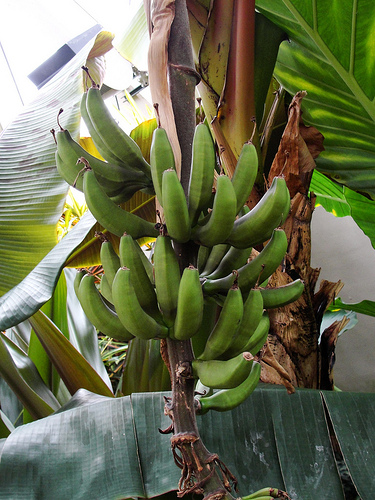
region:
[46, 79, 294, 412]
A large group of small green bananas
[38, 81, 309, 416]
Unripe green bananas growing on the tree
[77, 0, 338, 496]
A banana tree with many unripe bananas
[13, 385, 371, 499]
A large green banana leaf behind the banana tree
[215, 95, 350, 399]
A large brown banana tree trunk behind the bananas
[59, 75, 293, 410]
The green bananas all face upwards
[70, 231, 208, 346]
The bundle of green bananas is curving upwards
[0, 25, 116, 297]
A large yellow green banana leaf in the background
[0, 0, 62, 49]
The sun is shining too brightly to see the sky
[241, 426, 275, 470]
Small white splotches on the banana leaf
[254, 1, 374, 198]
large green leaf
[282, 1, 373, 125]
spine of a green leaf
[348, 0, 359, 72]
vein growing out from spine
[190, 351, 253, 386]
green banana attached to a brown stem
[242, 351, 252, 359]
brown nub on the end of a banana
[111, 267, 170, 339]
banana growing on a banana plant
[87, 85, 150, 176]
banana next to a banana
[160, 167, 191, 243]
banana under a banana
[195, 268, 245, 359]
banana to the right of a banana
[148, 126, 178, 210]
banana to the left of a banana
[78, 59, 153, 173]
The banana is green.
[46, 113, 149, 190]
The banana is green.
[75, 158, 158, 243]
The banana is green.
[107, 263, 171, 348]
The banana is green.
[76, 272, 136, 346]
The banana is green.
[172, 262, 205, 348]
The banana is green.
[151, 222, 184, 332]
The banana is green.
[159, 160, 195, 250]
The banana is green.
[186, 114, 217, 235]
The banana is green.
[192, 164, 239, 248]
The banana is green.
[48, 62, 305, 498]
a stalk of green bananas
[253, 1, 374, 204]
a broad green leaf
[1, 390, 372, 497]
a row of dark green textured leaves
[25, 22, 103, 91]
a square looking purple box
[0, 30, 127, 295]
a broad leaf with curve at the end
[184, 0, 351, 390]
a complicated tree trunk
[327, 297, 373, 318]
the tip of a bright green leaf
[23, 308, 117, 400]
the olive colored underside of a leaf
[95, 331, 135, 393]
a peak at a group of grasses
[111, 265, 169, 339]
a small green banana